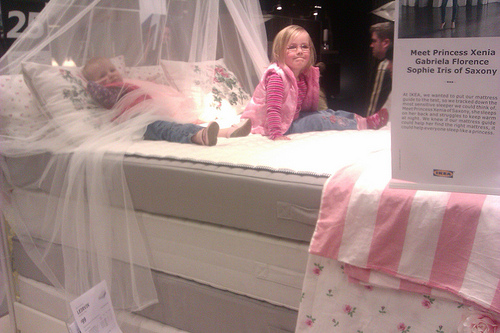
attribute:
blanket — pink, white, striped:
[406, 186, 481, 259]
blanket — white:
[356, 299, 431, 330]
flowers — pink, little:
[328, 296, 357, 317]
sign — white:
[373, 2, 484, 195]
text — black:
[420, 50, 483, 71]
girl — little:
[253, 30, 369, 149]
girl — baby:
[81, 41, 200, 149]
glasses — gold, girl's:
[285, 42, 309, 51]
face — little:
[283, 31, 313, 66]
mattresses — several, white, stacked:
[11, 143, 484, 326]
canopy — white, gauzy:
[6, 1, 273, 319]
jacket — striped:
[367, 56, 394, 110]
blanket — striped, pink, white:
[304, 148, 484, 316]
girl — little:
[238, 20, 390, 134]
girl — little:
[80, 50, 253, 140]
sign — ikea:
[388, 33, 482, 190]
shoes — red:
[367, 104, 390, 134]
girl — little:
[236, 19, 387, 143]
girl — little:
[81, 48, 254, 147]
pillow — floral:
[157, 52, 263, 120]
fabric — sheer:
[5, 3, 275, 322]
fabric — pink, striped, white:
[304, 130, 484, 310]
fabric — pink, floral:
[295, 258, 467, 327]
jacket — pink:
[240, 58, 330, 138]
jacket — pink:
[247, 62, 325, 132]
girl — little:
[249, 23, 389, 135]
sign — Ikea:
[394, 35, 498, 191]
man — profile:
[361, 22, 393, 114]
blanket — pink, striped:
[307, 173, 498, 311]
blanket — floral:
[294, 273, 386, 330]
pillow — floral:
[166, 52, 255, 119]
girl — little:
[80, 58, 254, 154]